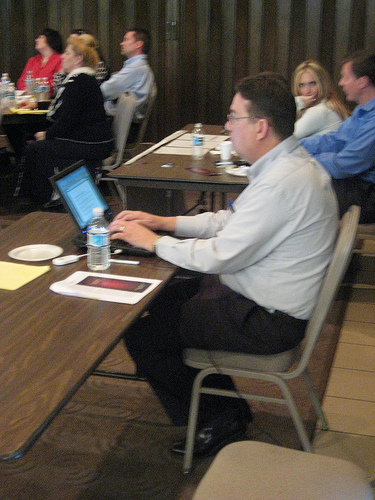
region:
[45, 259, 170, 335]
Paper on a table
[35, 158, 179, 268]
Laptop on a table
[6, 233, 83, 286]
Plate on a table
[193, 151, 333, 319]
Shirt on a man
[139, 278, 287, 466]
Black pants on a man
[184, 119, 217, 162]
Water bottle on a table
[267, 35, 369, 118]
Two people at a table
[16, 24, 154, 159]
Group of people at a table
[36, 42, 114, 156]
Woman in a black outfit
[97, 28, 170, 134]
Man in a blue shirt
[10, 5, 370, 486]
a conference room with people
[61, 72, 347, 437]
a middle aged man sitting on a chair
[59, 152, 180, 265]
a black laptop computer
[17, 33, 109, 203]
a woman with a black sweater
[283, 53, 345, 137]
a woman with blond hair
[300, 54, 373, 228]
a man with a blue long sleeve shirt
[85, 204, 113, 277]
a water bottle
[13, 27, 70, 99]
a woman with a red shirt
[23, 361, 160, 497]
hardwood floor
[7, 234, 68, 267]
an empty paper plate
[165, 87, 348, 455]
Man sitting in chair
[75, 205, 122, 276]
Clear water bottle on table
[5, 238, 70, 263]
White foam disposable plate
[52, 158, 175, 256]
Typing on IBM computer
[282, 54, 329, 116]
Woman looking at camera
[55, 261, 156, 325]
Paper on wood table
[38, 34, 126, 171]
Woman sitting in chair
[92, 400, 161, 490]
Shadow on carpet on floor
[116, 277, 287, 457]
Black long business pants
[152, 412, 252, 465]
Shiny leather dress shoes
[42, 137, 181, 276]
laptop open on table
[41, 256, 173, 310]
paper sitting on table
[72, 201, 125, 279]
plastic bottle of water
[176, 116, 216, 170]
plastic bottle of water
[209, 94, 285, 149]
pair of eye glasses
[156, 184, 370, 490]
metal chair with cushion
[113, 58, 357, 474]
man working on laptop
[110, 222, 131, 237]
small gold wedding ring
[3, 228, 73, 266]
small white disposable plate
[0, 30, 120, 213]
woman in black sweater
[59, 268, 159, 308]
Red and White Paper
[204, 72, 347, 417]
A man wearing glasses.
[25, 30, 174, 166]
Group of people watching something.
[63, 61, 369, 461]
Man typing on laptop.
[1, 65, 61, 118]
Six water bottles.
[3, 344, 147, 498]
Brown table and carpet.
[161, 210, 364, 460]
Grey padded chair.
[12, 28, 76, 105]
Woman wearing a red blouse.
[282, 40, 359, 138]
Blond hair woman looking a camera.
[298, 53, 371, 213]
Man wearing a dark blue shirt.